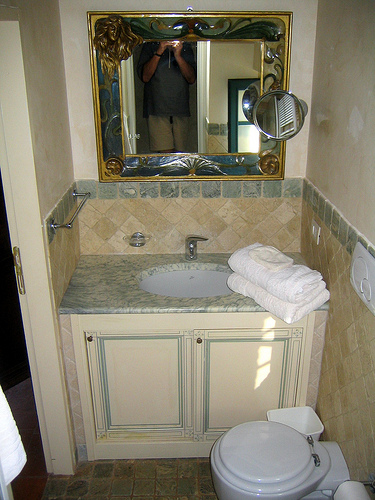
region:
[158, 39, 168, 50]
Hand of person taking picture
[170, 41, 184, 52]
Hand of person taking picture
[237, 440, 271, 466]
Part of white closed toilet lid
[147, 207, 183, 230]
Part of tile sink back splash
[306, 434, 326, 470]
Hinge for toilet lit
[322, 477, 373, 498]
Part of toilet tissue roll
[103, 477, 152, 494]
Part of bathroom tile floor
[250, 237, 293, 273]
White soap dish on towels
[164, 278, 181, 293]
Part of bathroom sink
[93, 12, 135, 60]
Part of ornate bathroom mirror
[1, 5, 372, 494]
A bathroom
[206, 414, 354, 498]
A white toilet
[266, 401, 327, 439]
A white trashbin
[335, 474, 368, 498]
A white roll of toilet paper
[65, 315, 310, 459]
Beige and green cabinet doors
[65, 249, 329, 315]
A marble countertop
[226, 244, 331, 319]
Folded towels stacked up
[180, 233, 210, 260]
Silver sink fixtures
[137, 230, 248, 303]
A bathroom sink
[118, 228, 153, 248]
A soap dish hanging on the wall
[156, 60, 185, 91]
the man is reflecting in the mirror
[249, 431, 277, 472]
the lid is down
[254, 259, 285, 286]
the towels are folded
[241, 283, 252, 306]
the towels are on the counter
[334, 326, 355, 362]
the wall is tan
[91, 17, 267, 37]
the mirror is decorative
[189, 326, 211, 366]
the door is closed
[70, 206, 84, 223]
the handle is silver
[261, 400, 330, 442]
a white trash can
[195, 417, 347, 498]
the toilet is round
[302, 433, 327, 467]
hinges of toilet are round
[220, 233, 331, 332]
white towels near a sink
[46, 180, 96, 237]
a handle of silver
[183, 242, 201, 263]
the faucet is color silver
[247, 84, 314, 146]
a round mirror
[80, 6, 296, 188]
a mirror shaped square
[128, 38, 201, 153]
a man reflected on a mirror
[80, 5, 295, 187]
border of mirror is yellow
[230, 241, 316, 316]
a towel in the sink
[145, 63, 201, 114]
a man with black shirt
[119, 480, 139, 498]
a cemented floor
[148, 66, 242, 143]
a clear mirror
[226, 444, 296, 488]
a white toilet cover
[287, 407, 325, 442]
a white gabag can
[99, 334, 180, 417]
yellow drawers in the scene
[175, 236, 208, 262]
a silver tap of water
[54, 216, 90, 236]
a silver towel holder